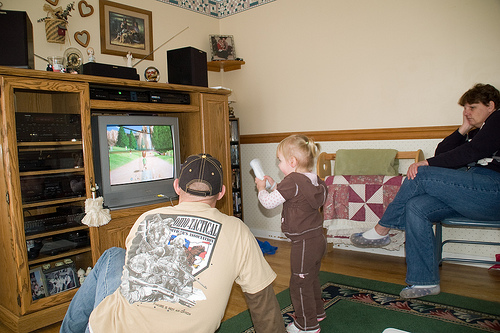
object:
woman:
[348, 81, 499, 300]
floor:
[225, 234, 499, 331]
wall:
[226, 0, 500, 198]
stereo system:
[4, 0, 214, 96]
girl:
[251, 135, 329, 332]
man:
[54, 154, 274, 331]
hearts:
[73, 31, 93, 47]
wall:
[19, 1, 220, 90]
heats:
[78, 1, 94, 17]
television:
[93, 114, 185, 209]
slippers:
[347, 232, 441, 299]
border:
[235, 125, 472, 144]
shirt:
[278, 174, 326, 236]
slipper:
[347, 231, 394, 251]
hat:
[177, 154, 224, 196]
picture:
[99, 2, 155, 62]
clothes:
[259, 172, 329, 330]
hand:
[254, 176, 272, 194]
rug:
[214, 269, 499, 332]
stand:
[0, 71, 234, 332]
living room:
[2, 0, 499, 332]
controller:
[249, 157, 270, 188]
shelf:
[11, 78, 101, 310]